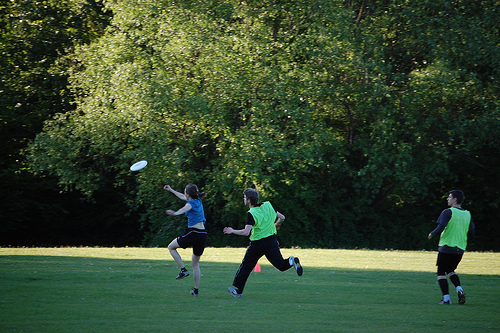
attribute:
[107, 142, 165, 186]
frisbee — white 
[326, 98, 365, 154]
leaves — green 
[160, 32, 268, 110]
leaves — green 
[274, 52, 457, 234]
leaves — green 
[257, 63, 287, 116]
leaves — green 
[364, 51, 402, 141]
leaves — green 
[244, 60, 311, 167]
leaves — green 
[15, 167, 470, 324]
field — green 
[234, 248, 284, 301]
cone — orange 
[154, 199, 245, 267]
shorts — black 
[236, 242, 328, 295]
shorts — black 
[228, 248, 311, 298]
pants — black 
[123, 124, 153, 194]
frisbee — white 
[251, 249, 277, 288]
cone — orange 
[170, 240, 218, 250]
shorts — black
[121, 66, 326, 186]
trees — green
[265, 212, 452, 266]
shirts — green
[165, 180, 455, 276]
people — running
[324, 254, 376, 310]
grass — green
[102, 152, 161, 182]
frisbee — white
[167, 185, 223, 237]
shirt — blue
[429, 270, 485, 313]
socks — tall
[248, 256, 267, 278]
cone — orange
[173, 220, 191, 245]
shorts — dark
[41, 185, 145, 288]
shadows — dark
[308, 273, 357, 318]
shadow — dark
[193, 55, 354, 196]
leaves — green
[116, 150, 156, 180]
frisbee — white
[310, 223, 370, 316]
grass — green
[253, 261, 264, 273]
orange item — bright orange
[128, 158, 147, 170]
white frisbee — round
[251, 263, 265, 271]
safety cone — orange